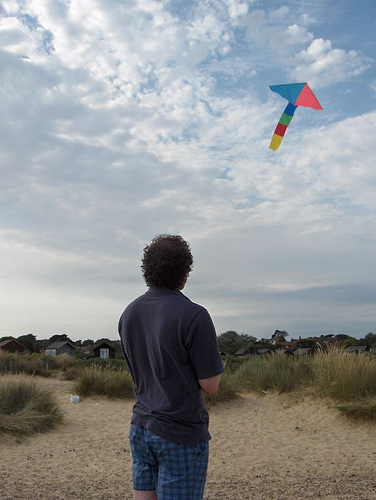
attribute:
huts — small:
[36, 337, 366, 355]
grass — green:
[1, 345, 375, 437]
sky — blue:
[318, 7, 371, 42]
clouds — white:
[10, 10, 374, 179]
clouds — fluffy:
[116, 21, 189, 99]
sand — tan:
[0, 373, 375, 498]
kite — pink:
[261, 76, 324, 159]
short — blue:
[129, 422, 208, 498]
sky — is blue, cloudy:
[2, 2, 372, 343]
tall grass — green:
[235, 345, 374, 397]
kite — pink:
[267, 80, 323, 150]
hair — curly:
[142, 232, 194, 290]